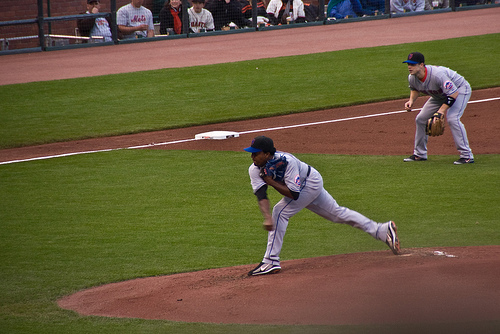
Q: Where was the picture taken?
A: It was taken at the stadium.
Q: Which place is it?
A: It is a stadium.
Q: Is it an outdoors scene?
A: Yes, it is outdoors.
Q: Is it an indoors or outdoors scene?
A: It is outdoors.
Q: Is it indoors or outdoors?
A: It is outdoors.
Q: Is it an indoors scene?
A: No, it is outdoors.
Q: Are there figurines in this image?
A: No, there are no figurines.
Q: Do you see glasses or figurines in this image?
A: No, there are no figurines or glasses.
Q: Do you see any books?
A: No, there are no books.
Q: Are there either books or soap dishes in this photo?
A: No, there are no books or soap dishes.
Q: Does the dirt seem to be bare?
A: Yes, the dirt is bare.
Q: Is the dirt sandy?
A: No, the dirt is bare.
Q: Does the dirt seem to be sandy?
A: No, the dirt is bare.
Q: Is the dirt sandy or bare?
A: The dirt is bare.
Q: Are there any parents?
A: No, there are no parents.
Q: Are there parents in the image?
A: No, there are no parents.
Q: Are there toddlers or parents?
A: No, there are no parents or toddlers.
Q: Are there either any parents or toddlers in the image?
A: No, there are no parents or toddlers.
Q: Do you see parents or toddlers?
A: No, there are no parents or toddlers.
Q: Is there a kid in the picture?
A: No, there are no children.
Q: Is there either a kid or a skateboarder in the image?
A: No, there are no children or skateboarders.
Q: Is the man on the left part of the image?
A: Yes, the man is on the left of the image.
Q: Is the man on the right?
A: No, the man is on the left of the image.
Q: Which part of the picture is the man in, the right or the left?
A: The man is on the left of the image.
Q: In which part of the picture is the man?
A: The man is on the left of the image.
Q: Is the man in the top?
A: Yes, the man is in the top of the image.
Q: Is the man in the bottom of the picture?
A: No, the man is in the top of the image.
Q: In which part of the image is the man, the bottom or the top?
A: The man is in the top of the image.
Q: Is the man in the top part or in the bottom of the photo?
A: The man is in the top of the image.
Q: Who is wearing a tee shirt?
A: The man is wearing a tee shirt.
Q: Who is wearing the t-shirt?
A: The man is wearing a tee shirt.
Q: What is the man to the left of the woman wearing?
A: The man is wearing a tshirt.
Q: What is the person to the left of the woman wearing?
A: The man is wearing a tshirt.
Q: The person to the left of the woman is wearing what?
A: The man is wearing a tshirt.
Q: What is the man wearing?
A: The man is wearing a tshirt.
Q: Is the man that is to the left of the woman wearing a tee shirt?
A: Yes, the man is wearing a tee shirt.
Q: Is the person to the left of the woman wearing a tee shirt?
A: Yes, the man is wearing a tee shirt.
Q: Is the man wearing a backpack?
A: No, the man is wearing a tee shirt.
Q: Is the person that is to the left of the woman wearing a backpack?
A: No, the man is wearing a tee shirt.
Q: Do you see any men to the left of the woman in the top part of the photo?
A: Yes, there is a man to the left of the woman.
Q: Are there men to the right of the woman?
A: No, the man is to the left of the woman.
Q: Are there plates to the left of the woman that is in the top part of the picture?
A: No, there is a man to the left of the woman.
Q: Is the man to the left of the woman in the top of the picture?
A: Yes, the man is to the left of the woman.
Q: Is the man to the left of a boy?
A: No, the man is to the left of the woman.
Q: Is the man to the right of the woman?
A: No, the man is to the left of the woman.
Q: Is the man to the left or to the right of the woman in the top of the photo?
A: The man is to the left of the woman.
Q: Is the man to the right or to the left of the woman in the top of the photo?
A: The man is to the left of the woman.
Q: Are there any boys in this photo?
A: No, there are no boys.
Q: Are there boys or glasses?
A: No, there are no boys or glasses.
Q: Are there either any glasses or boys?
A: No, there are no boys or glasses.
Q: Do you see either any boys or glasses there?
A: No, there are no boys or glasses.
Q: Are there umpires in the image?
A: No, there are no umpires.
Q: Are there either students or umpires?
A: No, there are no umpires or students.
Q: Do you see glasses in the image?
A: No, there are no glasses.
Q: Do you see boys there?
A: No, there are no boys.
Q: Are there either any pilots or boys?
A: No, there are no boys or pilots.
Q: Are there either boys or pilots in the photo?
A: No, there are no boys or pilots.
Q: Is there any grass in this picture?
A: Yes, there is grass.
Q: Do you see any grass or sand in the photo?
A: Yes, there is grass.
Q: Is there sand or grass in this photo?
A: Yes, there is grass.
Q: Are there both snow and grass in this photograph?
A: No, there is grass but no snow.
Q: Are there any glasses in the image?
A: No, there are no glasses.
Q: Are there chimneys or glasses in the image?
A: No, there are no glasses or chimneys.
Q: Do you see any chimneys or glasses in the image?
A: No, there are no glasses or chimneys.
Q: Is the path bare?
A: Yes, the path is bare.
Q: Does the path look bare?
A: Yes, the path is bare.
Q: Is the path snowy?
A: No, the path is bare.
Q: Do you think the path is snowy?
A: No, the path is bare.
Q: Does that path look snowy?
A: No, the path is bare.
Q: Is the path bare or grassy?
A: The path is bare.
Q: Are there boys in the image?
A: No, there are no boys.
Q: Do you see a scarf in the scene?
A: Yes, there is a scarf.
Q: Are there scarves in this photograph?
A: Yes, there is a scarf.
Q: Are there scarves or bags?
A: Yes, there is a scarf.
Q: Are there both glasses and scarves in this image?
A: No, there is a scarf but no glasses.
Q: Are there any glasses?
A: No, there are no glasses.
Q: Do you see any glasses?
A: No, there are no glasses.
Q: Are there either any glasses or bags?
A: No, there are no glasses or bags.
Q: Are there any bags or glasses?
A: No, there are no glasses or bags.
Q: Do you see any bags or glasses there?
A: No, there are no glasses or bags.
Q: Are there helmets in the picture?
A: No, there are no helmets.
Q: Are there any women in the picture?
A: Yes, there is a woman.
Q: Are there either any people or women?
A: Yes, there is a woman.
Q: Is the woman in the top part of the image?
A: Yes, the woman is in the top of the image.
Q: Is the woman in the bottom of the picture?
A: No, the woman is in the top of the image.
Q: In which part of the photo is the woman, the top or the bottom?
A: The woman is in the top of the image.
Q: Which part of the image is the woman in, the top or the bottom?
A: The woman is in the top of the image.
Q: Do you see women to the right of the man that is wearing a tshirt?
A: Yes, there is a woman to the right of the man.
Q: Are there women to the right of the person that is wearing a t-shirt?
A: Yes, there is a woman to the right of the man.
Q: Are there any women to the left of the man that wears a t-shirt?
A: No, the woman is to the right of the man.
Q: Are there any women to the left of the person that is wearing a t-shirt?
A: No, the woman is to the right of the man.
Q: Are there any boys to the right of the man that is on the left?
A: No, there is a woman to the right of the man.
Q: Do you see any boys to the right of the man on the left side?
A: No, there is a woman to the right of the man.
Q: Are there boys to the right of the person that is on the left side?
A: No, there is a woman to the right of the man.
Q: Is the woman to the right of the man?
A: Yes, the woman is to the right of the man.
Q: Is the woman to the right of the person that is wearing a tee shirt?
A: Yes, the woman is to the right of the man.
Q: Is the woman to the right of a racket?
A: No, the woman is to the right of the man.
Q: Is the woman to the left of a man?
A: No, the woman is to the right of a man.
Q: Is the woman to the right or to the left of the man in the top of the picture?
A: The woman is to the right of the man.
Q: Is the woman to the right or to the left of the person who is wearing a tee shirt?
A: The woman is to the right of the man.